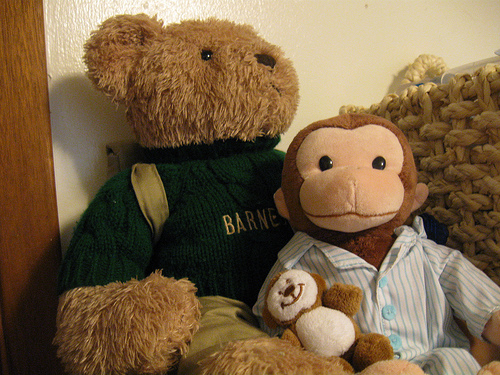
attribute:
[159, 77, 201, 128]
toy — stuffed, teddy bear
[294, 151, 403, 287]
toy — stuffed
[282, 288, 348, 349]
toy — stuffed, small, brown, white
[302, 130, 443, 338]
monkey — large, brown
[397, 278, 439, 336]
pajamas — blue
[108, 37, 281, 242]
teddy bear — fuzzy, brown, large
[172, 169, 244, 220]
sweater — green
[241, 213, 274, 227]
embroidery — yellow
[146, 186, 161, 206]
overalls — khaki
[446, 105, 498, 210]
basket — wicker, brown, woven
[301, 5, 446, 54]
wall — white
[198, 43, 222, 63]
eye — open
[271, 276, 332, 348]
teddy bear — brown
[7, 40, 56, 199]
door frame — wooden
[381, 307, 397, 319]
button — big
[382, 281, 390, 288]
button — big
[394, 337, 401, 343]
button — big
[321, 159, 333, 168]
eye — open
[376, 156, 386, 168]
eye — open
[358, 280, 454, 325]
pajama shirt — white, green